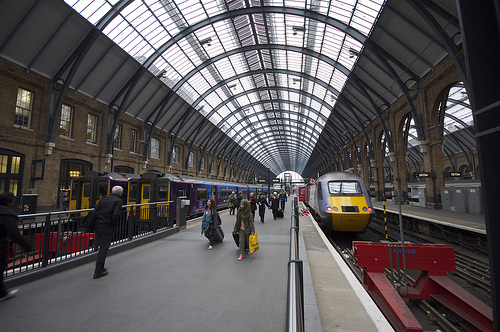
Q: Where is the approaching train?
A: On the right side.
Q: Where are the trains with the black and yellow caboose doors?
A: On the left side.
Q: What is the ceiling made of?
A: Windows.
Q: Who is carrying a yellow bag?
A: A lady walking on the platform.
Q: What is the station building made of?
A: Brown brick.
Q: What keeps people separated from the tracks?
A: Black iron fences.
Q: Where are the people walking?
A: On the center platform.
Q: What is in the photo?
A: Train.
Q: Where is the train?
A: On the track.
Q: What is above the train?
A: The roof.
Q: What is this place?
A: A station.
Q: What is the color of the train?
A: Yellow and black.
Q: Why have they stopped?
A: To pick people.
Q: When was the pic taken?
A: During the day.